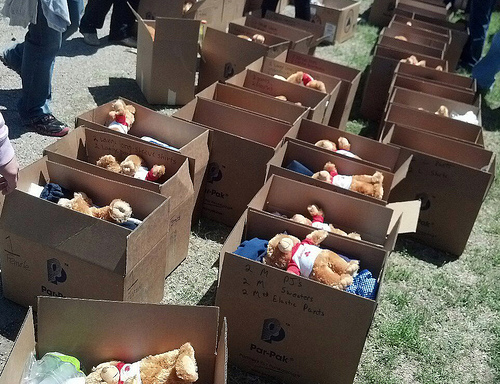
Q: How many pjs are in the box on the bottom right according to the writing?
A: Two.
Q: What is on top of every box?
A: Stuffed bear.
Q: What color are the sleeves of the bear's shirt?
A: Red.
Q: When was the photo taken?
A: Daytime.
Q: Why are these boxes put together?
A: Charity.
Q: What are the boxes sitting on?
A: Grass.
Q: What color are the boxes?
A: Brown.